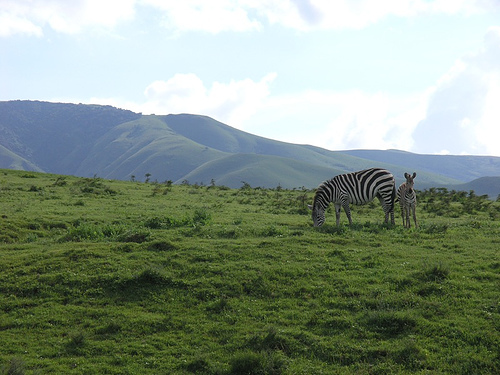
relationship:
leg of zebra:
[379, 190, 398, 224] [312, 168, 397, 228]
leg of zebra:
[332, 199, 344, 223] [312, 168, 397, 228]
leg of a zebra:
[379, 190, 398, 224] [312, 168, 397, 228]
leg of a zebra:
[343, 204, 354, 226] [312, 168, 397, 228]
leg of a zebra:
[388, 202, 397, 224] [312, 168, 397, 228]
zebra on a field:
[312, 168, 397, 228] [9, 169, 494, 371]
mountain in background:
[1, 95, 496, 202] [3, 1, 499, 199]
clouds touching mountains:
[4, 9, 496, 151] [1, 95, 496, 202]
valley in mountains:
[26, 144, 161, 181] [1, 95, 496, 202]